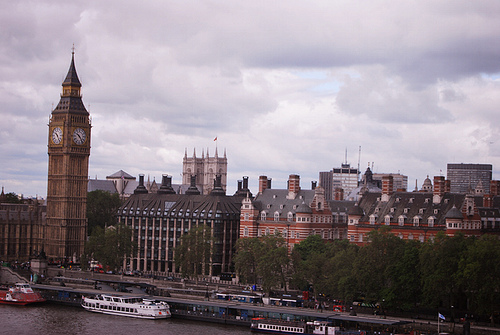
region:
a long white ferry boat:
[81, 285, 183, 320]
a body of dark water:
[11, 305, 63, 330]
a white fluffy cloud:
[118, 46, 275, 131]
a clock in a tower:
[36, 103, 103, 165]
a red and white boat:
[3, 270, 47, 320]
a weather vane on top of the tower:
[61, 33, 83, 55]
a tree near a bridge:
[83, 220, 140, 270]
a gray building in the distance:
[443, 150, 498, 192]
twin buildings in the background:
[161, 141, 241, 195]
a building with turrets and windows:
[248, 183, 355, 260]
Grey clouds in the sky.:
[3, 5, 496, 200]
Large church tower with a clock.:
[37, 19, 91, 268]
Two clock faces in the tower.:
[40, 111, 102, 153]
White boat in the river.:
[64, 290, 181, 328]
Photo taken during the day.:
[0, 10, 493, 327]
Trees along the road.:
[89, 218, 496, 333]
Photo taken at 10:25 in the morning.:
[34, 41, 119, 290]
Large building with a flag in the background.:
[154, 105, 238, 205]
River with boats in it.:
[10, 285, 265, 333]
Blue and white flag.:
[437, 308, 450, 333]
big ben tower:
[37, 34, 123, 274]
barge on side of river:
[75, 290, 205, 331]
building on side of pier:
[120, 162, 230, 288]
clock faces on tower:
[46, 121, 89, 147]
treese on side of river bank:
[231, 227, 487, 318]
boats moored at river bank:
[1, 267, 359, 327]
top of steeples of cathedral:
[167, 137, 240, 189]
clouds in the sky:
[81, 5, 484, 155]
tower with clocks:
[33, 37, 94, 277]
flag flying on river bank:
[430, 308, 447, 333]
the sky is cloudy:
[128, 17, 335, 112]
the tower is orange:
[42, 44, 103, 286]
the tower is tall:
[44, 32, 92, 263]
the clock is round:
[49, 110, 87, 162]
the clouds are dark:
[150, 32, 462, 152]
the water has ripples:
[42, 307, 99, 330]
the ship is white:
[77, 271, 179, 331]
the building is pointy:
[171, 127, 259, 208]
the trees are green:
[282, 235, 384, 284]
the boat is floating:
[70, 276, 177, 333]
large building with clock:
[31, 37, 113, 269]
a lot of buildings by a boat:
[28, 42, 480, 310]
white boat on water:
[63, 263, 201, 326]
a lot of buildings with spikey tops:
[36, 30, 463, 292]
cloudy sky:
[92, 18, 426, 210]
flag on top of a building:
[145, 112, 247, 172]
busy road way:
[40, 245, 397, 322]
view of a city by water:
[14, 33, 481, 298]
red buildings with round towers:
[224, 162, 460, 269]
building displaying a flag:
[161, 120, 283, 195]